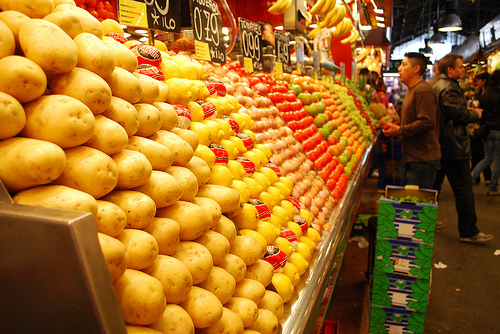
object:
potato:
[109, 184, 155, 227]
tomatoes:
[292, 117, 318, 141]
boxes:
[374, 238, 436, 278]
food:
[373, 187, 438, 208]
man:
[384, 50, 439, 190]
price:
[232, 19, 266, 63]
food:
[127, 88, 348, 184]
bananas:
[310, 1, 332, 31]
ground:
[445, 245, 500, 320]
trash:
[431, 259, 450, 271]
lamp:
[437, 10, 461, 42]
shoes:
[459, 228, 500, 242]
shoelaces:
[479, 230, 486, 238]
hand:
[380, 120, 400, 139]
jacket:
[433, 71, 479, 149]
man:
[431, 51, 495, 247]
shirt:
[396, 79, 443, 162]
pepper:
[383, 123, 398, 131]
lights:
[391, 31, 467, 62]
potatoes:
[184, 282, 232, 328]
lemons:
[229, 177, 250, 203]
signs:
[193, 37, 213, 62]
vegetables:
[0, 33, 400, 272]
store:
[0, 0, 497, 334]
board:
[187, 0, 225, 63]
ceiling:
[391, 0, 499, 15]